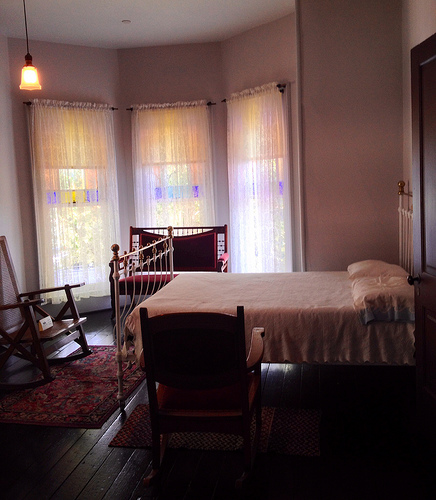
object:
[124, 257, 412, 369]
sheet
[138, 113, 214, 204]
stained glass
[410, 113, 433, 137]
ground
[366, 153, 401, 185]
ground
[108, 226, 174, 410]
frame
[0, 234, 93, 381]
chair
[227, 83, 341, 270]
wall curtain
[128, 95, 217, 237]
curtain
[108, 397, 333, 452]
carpet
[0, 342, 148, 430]
carpet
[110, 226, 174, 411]
foot board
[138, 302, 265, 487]
chair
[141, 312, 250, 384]
wood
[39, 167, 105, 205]
window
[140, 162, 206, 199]
window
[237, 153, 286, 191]
window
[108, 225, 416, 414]
bed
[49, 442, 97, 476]
floor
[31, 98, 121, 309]
curtain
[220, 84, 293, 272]
curtain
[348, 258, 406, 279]
pillow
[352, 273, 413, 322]
pillow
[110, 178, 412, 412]
frame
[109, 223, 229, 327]
bench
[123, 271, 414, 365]
blanket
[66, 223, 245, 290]
cradle